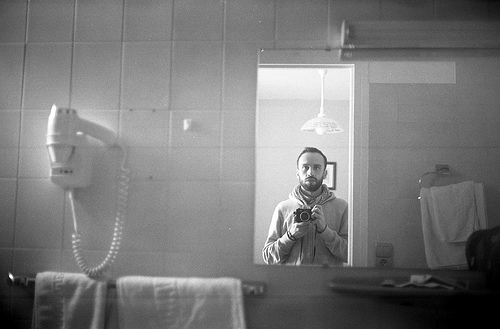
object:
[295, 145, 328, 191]
head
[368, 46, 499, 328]
wall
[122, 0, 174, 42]
rectangular tiles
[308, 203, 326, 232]
hands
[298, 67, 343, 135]
lamp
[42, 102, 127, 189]
melted butter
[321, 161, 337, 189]
picture frame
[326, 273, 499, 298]
ring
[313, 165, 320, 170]
eyes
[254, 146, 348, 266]
reflection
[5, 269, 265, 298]
rack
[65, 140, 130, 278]
cord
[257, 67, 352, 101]
ceiling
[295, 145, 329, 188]
man's head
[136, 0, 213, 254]
wall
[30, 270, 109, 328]
towel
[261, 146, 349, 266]
face person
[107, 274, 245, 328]
towel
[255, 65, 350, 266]
man mirror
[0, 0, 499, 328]
bathroom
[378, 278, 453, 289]
toothbrush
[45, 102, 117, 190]
blow dryer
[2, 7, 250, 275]
wall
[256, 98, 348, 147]
wall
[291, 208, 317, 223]
camera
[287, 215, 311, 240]
hands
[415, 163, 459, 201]
towel ring